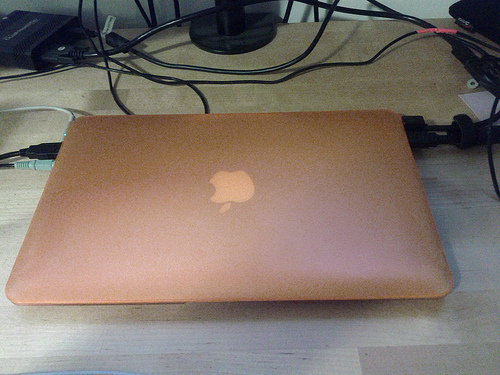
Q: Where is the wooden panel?
A: In the table.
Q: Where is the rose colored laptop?
A: On the desk.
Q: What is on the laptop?
A: Apple logo.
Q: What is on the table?
A: Laptop.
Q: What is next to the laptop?
A: Black cords.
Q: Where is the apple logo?
A: On the gold laptop.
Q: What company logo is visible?
A: Apple.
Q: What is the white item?
A: Laptop.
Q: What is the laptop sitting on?
A: Table.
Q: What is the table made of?
A: Wood.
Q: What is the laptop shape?
A: Rectangle.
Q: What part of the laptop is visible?
A: Top.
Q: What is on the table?
A: A laptop.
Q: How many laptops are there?
A: 1.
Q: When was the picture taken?
A: Day time.